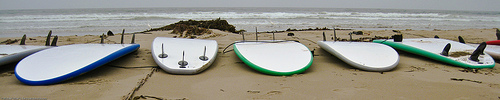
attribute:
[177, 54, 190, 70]
mark — black, spotted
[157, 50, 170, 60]
mark — spotted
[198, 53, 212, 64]
mark — spotted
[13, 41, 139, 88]
surface of board — blue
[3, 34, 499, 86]
surfboards — in a line, in a row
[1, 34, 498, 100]
edge of shore — tan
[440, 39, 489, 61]
fins of surfboard — sticking up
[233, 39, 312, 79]
surfboard — green, white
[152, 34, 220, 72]
bottom of board — white, grey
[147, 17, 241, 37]
rock — large